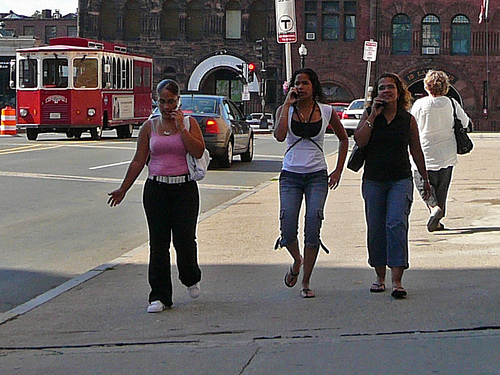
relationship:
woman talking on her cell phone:
[104, 78, 213, 315] [171, 97, 182, 110]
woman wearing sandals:
[273, 66, 346, 299] [281, 254, 303, 286]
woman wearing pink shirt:
[104, 78, 213, 315] [149, 115, 188, 177]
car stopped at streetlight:
[144, 91, 254, 165] [247, 61, 254, 71]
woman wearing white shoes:
[104, 78, 213, 315] [187, 284, 200, 300]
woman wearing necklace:
[104, 78, 213, 315] [157, 116, 177, 137]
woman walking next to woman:
[104, 78, 213, 315] [273, 66, 346, 299]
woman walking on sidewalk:
[104, 78, 213, 315] [3, 131, 497, 369]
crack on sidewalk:
[238, 344, 266, 374] [3, 131, 497, 369]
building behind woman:
[77, 1, 499, 135] [104, 78, 213, 315]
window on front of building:
[224, 9, 241, 39] [77, 1, 499, 135]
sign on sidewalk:
[275, 2, 296, 44] [3, 131, 497, 369]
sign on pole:
[275, 2, 296, 44] [286, 43, 292, 86]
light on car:
[207, 121, 221, 135] [144, 91, 254, 165]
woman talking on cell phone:
[273, 66, 346, 299] [291, 83, 299, 98]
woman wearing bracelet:
[353, 70, 435, 299] [420, 178, 432, 185]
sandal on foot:
[300, 287, 314, 298] [298, 285, 314, 300]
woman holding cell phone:
[353, 70, 435, 299] [374, 93, 381, 114]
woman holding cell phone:
[273, 66, 346, 299] [291, 83, 299, 98]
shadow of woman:
[434, 226, 499, 234] [410, 69, 471, 233]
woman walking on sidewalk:
[273, 66, 346, 299] [3, 131, 497, 369]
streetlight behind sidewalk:
[247, 61, 254, 71] [3, 131, 497, 369]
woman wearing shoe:
[410, 69, 471, 233] [426, 206, 444, 233]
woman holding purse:
[410, 69, 471, 233] [450, 96, 474, 156]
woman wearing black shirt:
[353, 70, 435, 299] [364, 101, 412, 179]